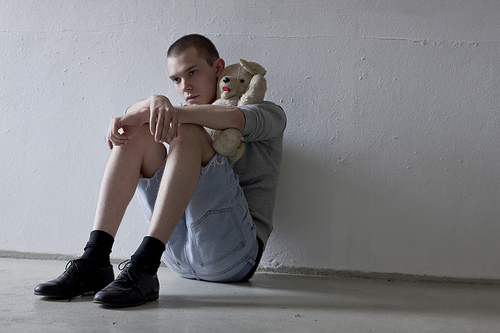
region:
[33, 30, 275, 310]
man sitting on floor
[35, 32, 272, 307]
man holding teddy bear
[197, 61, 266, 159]
ivory stuffed teddy bear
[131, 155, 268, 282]
light blue denim shorts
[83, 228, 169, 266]
black slouched dress socks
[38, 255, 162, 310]
black lace-up dress shoes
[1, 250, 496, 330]
white concrete unfinished floor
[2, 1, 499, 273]
white spackeled concrete wall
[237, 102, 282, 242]
grey long sleeve tee shirt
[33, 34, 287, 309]
man sitting against wall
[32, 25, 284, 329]
The boy is sitting on the floor.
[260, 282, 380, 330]
The floor is gray.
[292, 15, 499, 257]
The wall is white.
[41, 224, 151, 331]
The boy has on black socks and shoes.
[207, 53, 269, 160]
The bear is light brown.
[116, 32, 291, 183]
The boy is holding the teddy bear.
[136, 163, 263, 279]
The boy has on blue jean shorts.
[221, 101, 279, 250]
The boy has on a gray shirt.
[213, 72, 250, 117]
The teddy bear has a red tongue.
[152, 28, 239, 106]
The boy has dark brown hair.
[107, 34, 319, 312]
boy sitting on cement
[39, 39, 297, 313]
boy wearing black shoes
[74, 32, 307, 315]
boy wearing black socks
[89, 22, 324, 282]
boy wearing blue jean shorts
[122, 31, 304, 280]
boy wearing gray shirt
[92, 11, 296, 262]
boy holding teddy bear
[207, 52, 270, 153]
teddy bear has red tongue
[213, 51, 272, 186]
teddy bear has black nose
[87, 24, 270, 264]
boy sitting with arms on knees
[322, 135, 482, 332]
white cement wall and gray floor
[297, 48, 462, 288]
the wall is smooth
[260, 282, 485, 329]
the ground is cement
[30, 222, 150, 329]
he is wearing black shoes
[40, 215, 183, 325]
he is wearing black socks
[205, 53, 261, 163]
the bear is white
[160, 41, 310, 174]
he is holding a bear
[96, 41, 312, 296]
he is sitting on the ground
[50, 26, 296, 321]
the man is young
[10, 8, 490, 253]
the man is alone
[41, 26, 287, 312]
he is not smiling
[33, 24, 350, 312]
A boy holding a teddy bear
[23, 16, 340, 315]
A boy wearing blue jean shorts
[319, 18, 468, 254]
A wall painted white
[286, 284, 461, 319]
A gray concrete floor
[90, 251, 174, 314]
A black shoe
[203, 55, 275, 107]
A brown teddy bear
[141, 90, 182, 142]
A boy's hand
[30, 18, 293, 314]
A boy with brown hair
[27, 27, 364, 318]
A boy wearing black shoes and black socks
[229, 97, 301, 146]
A man's sleave